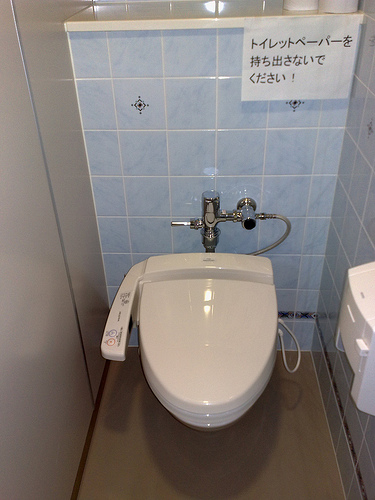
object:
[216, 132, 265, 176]
tile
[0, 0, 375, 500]
toilet stall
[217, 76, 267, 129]
tile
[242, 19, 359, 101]
instructions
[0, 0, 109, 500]
side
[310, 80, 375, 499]
side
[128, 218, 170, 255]
side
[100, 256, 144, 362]
side bar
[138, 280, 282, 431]
seat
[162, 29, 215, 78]
tile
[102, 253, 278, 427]
white toilet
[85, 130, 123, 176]
tile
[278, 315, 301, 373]
hose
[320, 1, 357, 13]
rolls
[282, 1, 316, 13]
toilet paper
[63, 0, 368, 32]
white shelf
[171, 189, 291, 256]
chrome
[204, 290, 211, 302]
light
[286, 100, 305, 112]
accent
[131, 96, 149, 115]
accent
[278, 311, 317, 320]
accent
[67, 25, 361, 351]
tile wall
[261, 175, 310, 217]
tile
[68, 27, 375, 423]
tiles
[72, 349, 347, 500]
floor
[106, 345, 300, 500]
shadow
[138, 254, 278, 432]
bowl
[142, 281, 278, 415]
lid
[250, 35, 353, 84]
letters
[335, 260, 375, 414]
paper dispenser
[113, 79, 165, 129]
tile